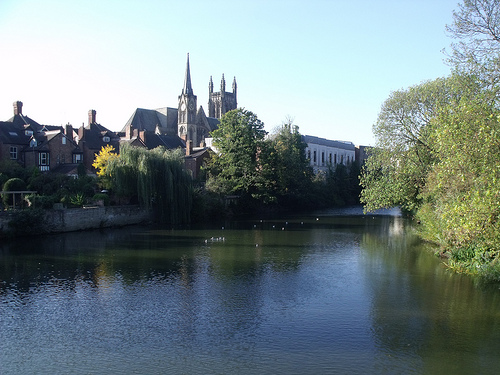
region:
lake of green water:
[192, 265, 339, 305]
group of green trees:
[368, 71, 485, 253]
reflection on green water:
[77, 257, 190, 298]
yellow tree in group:
[91, 146, 113, 172]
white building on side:
[302, 133, 354, 168]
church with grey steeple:
[164, 48, 206, 163]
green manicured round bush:
[0, 177, 30, 204]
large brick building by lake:
[26, 122, 88, 174]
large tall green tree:
[204, 117, 311, 224]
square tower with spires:
[202, 64, 243, 122]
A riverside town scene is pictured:
[6, 28, 491, 361]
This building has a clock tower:
[176, 45, 199, 147]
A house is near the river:
[0, 94, 132, 194]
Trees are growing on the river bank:
[365, 84, 497, 274]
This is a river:
[31, 242, 445, 364]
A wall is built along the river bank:
[2, 207, 157, 229]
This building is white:
[300, 129, 357, 183]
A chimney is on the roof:
[10, 96, 28, 122]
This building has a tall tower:
[204, 68, 243, 128]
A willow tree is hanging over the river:
[109, 147, 206, 228]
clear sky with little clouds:
[0, 0, 497, 147]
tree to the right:
[360, 0, 498, 275]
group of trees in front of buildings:
[95, 108, 322, 207]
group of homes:
[1, 52, 394, 198]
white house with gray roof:
[297, 133, 355, 178]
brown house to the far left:
[1, 101, 121, 181]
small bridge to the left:
[0, 178, 35, 206]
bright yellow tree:
[91, 145, 117, 179]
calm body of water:
[1, 216, 496, 373]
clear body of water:
[1, 215, 498, 373]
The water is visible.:
[140, 264, 355, 373]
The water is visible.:
[256, 289, 288, 326]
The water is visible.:
[202, 283, 276, 364]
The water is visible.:
[177, 221, 312, 362]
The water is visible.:
[224, 268, 298, 325]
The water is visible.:
[204, 296, 329, 371]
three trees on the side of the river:
[357, 1, 497, 273]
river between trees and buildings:
[2, 50, 498, 373]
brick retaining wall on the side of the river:
[0, 206, 152, 238]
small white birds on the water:
[202, 215, 320, 247]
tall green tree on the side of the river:
[200, 107, 285, 211]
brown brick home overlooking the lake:
[2, 100, 121, 195]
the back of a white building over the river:
[295, 132, 356, 187]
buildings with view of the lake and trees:
[0, 51, 356, 196]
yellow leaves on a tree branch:
[91, 144, 113, 176]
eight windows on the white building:
[305, 147, 356, 166]